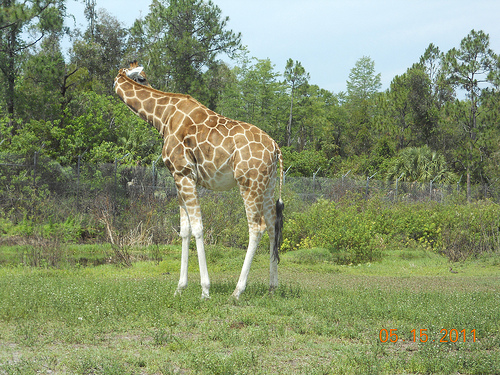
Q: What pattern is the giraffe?
A: Spotted.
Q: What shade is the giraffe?
A: Tan and brown.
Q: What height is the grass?
A: Short.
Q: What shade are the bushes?
A: Green.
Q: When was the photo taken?
A: During the daytime.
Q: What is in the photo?
A: A giraffe.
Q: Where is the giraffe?
A: In the field.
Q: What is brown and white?
A: The giraffe.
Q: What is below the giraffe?
A: Grass.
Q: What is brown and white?
A: Giraffe.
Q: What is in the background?
A: Many trees.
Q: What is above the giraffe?
A: The sky.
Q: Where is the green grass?
A: In the field.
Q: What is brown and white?
A: Giraffe.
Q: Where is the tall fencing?
A: Behind the giraffe.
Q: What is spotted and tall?
A: Giraffe.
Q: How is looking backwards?
A: Giraffe.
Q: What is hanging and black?
A: Tail.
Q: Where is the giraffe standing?
A: In the grass.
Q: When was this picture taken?
A: During the day.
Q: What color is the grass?
A: Green.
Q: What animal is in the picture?
A: Giraffe.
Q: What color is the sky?
A: Blue.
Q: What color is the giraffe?
A: Brown and tan.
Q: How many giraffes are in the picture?
A: One.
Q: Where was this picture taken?
A: A zoo.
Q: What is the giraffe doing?
A: Bending its neck.